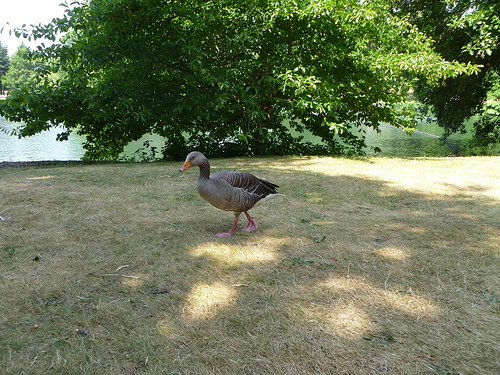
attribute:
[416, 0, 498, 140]
tree — bushy, green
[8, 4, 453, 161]
bush — large, very large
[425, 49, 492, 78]
leaves — green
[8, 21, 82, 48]
leaves — green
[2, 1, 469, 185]
tree — green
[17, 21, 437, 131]
tree — large, leafy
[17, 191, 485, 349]
grass — yellowed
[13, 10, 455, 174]
tree — brown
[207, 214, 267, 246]
legs — orange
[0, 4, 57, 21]
clouds — white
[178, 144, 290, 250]
duck — single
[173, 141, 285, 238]
duck — grey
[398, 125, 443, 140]
gray stick — long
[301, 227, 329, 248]
leaves — green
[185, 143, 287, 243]
duck — small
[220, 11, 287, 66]
leaves — green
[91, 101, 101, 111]
leaf — green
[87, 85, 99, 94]
leaf — green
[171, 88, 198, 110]
leaf — green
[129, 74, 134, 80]
leaf — green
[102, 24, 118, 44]
leaf — green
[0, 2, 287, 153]
tree — brown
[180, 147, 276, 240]
goose — grey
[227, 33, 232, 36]
leaf — green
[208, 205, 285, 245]
feet — reddish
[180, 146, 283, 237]
goose — grey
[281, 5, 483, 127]
sunshine area — large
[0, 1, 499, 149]
bush — large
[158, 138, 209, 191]
beak — goose's, orange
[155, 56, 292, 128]
leaves — green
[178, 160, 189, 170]
beak — orange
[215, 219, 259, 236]
feet — webbed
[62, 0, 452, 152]
leaves — green